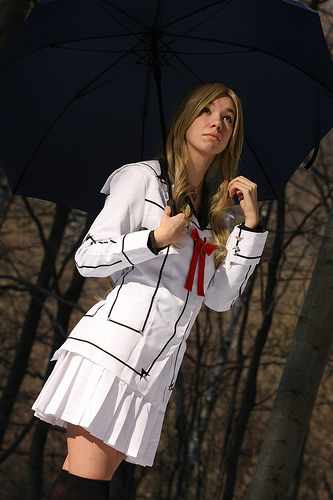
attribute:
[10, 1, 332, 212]
umbrella — black, blue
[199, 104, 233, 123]
eyes — looking up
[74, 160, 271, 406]
jacket — white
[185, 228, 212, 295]
bow — red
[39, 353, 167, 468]
skirt — short, white, pleated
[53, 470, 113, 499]
stockings — knee high, nylon, black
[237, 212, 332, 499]
trunk — brown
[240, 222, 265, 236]
shirt — black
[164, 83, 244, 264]
hair — light brown, long, blonde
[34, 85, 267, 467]
woman — looking, standing